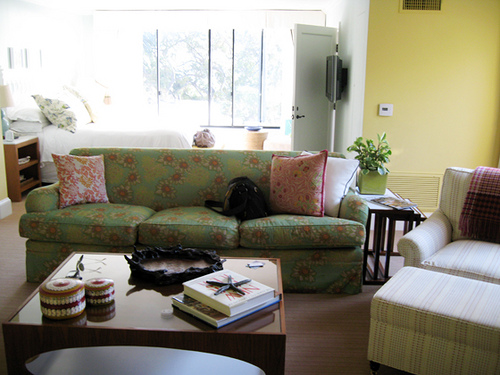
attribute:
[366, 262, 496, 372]
foot stool — white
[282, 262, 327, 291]
flower — yellow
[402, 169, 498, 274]
chair — striped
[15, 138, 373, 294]
couch — green, flower patterned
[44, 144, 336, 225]
pillows — pink, green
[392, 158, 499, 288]
chair — white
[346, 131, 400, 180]
plant — green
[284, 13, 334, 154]
door — white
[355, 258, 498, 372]
ottoman — white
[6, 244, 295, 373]
coffee table — wooden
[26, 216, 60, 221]
floral pattern — small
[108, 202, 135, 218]
floral pattern — small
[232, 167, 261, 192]
floral pattern — small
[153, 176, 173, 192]
floral pattern — small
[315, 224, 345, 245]
floral pattern — small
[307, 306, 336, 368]
floor — wooden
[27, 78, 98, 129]
pillow —  on the bed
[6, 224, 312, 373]
table — brown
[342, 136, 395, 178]
plant — green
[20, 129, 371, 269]
couch — green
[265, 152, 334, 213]
pillow — on the couch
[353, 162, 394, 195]
pot — on the table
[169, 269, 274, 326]
books — on the table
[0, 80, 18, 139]
lamp — on the shelf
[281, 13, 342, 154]
door — open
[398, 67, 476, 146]
wall — yellow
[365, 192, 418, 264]
table — brown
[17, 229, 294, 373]
table — square, center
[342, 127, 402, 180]
plant — green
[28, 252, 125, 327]
items — several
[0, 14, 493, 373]
scene — peaceful, of living room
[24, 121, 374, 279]
couch — a green flower print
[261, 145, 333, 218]
pillows — on a couch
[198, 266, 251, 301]
starfish — on books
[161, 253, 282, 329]
books — in a stack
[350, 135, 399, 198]
house plant — small potted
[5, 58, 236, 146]
bed — white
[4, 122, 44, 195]
nightstand — wooden, small 